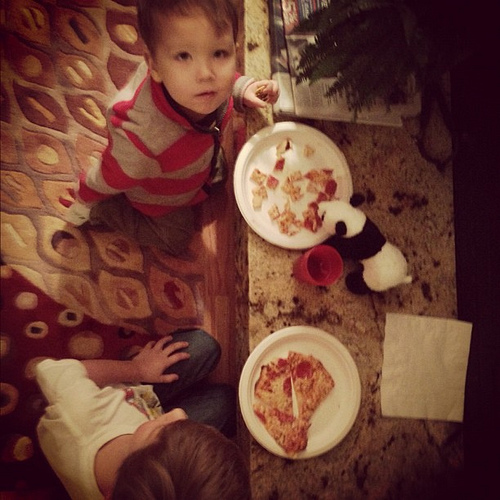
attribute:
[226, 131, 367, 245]
plate — round , white 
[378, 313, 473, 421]
napkin — white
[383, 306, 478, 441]
paper towel — white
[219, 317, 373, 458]
plate — white , round 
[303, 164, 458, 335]
panda — white , small , black 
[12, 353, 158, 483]
sleeve shirt — white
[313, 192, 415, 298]
panda — black , white 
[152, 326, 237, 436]
jeans — blue 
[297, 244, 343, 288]
glass — red , plastic 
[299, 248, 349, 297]
cup — small , red , plastic 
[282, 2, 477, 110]
plant leaves — green 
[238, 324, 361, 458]
plate — white